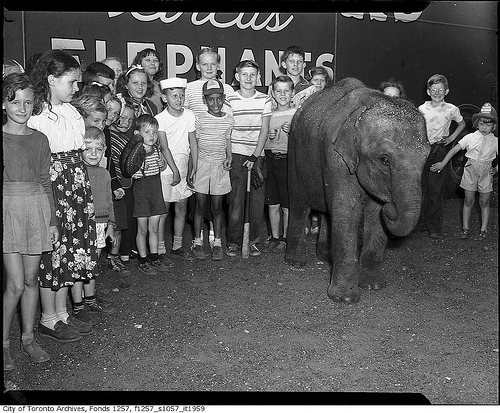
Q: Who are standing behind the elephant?
A: Kids.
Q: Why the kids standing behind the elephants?
A: To take a picture with.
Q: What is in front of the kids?
A: Elephant.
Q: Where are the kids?
A: Behind the elephant.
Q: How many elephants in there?
A: One.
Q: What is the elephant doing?
A: Standing.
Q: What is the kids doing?
A: Looking at the elephant.